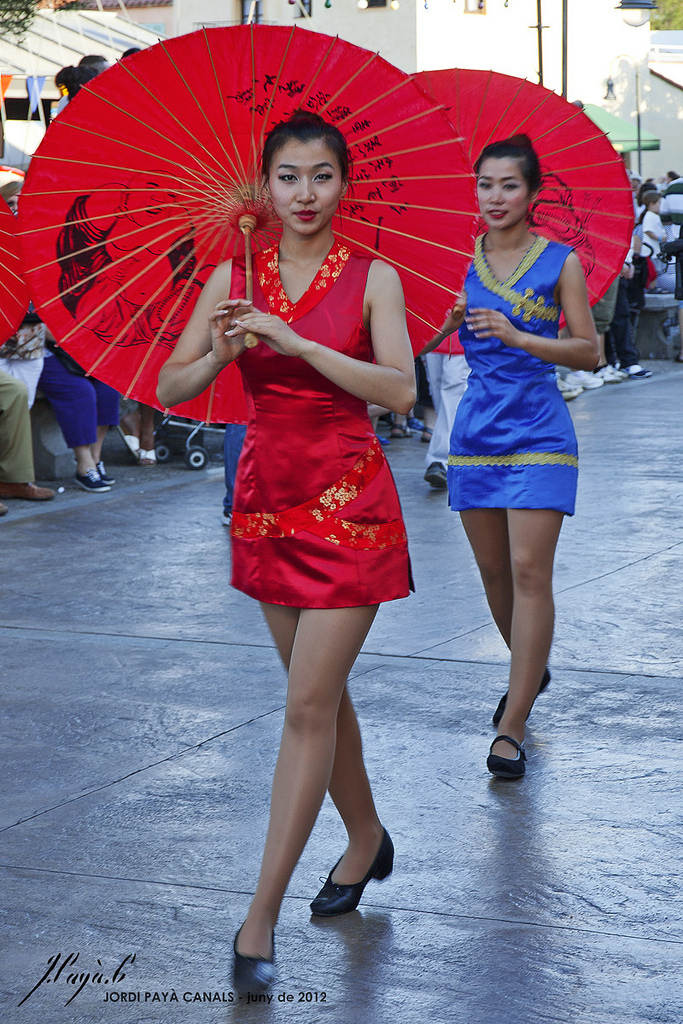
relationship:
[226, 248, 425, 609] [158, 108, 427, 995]
red dress on woman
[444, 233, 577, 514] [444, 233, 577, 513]
gold dress by gold dress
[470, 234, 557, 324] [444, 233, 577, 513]
gold stripe on gold dress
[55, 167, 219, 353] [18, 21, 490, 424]
image on umbrella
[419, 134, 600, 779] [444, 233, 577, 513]
woman wearing gold dress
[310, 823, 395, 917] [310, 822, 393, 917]
shoe on shoe